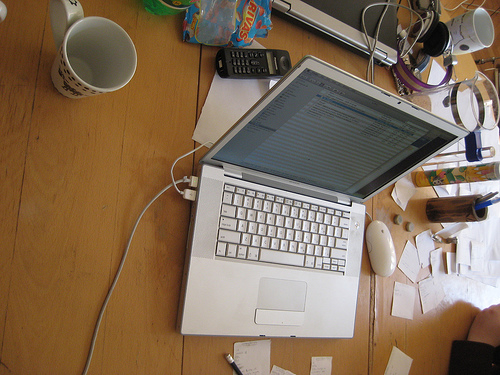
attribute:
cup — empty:
[50, 0, 138, 101]